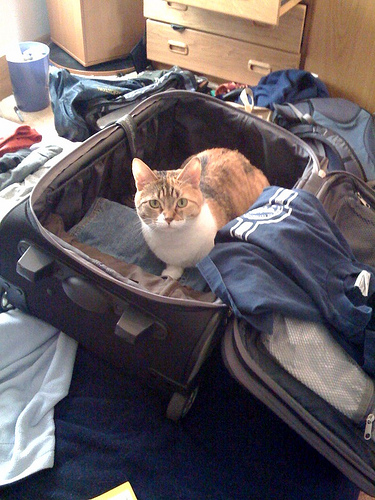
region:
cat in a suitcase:
[27, 92, 318, 351]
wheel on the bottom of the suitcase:
[155, 383, 211, 430]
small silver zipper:
[363, 416, 372, 441]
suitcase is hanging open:
[16, 67, 373, 495]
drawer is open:
[166, 0, 323, 24]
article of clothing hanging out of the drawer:
[171, 24, 190, 30]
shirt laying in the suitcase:
[196, 178, 373, 332]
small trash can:
[6, 40, 55, 113]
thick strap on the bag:
[285, 118, 367, 180]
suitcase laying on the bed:
[0, 88, 372, 495]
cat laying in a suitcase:
[0, 90, 374, 484]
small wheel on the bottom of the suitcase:
[158, 384, 206, 426]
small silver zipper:
[361, 412, 373, 442]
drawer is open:
[179, 0, 313, 28]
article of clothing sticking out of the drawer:
[168, 21, 184, 33]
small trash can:
[5, 33, 56, 115]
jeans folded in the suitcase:
[66, 191, 223, 296]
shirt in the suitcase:
[195, 184, 373, 342]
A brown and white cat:
[129, 148, 271, 279]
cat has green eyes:
[145, 197, 187, 208]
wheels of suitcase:
[0, 283, 197, 422]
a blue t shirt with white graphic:
[196, 182, 372, 314]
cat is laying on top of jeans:
[61, 148, 267, 298]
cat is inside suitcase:
[11, 79, 333, 351]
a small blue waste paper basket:
[4, 37, 54, 112]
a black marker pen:
[10, 106, 24, 121]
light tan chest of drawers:
[141, 5, 307, 91]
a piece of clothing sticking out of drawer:
[167, 19, 188, 32]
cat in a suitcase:
[129, 132, 274, 288]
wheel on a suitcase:
[157, 368, 210, 444]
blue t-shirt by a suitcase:
[218, 170, 369, 374]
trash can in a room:
[2, 34, 58, 110]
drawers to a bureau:
[131, 1, 299, 100]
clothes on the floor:
[46, 57, 176, 132]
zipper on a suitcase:
[352, 409, 373, 439]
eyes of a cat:
[144, 193, 193, 213]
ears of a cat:
[124, 150, 213, 188]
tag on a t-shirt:
[353, 261, 372, 306]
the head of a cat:
[129, 148, 232, 250]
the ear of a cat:
[131, 156, 210, 198]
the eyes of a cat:
[126, 182, 208, 229]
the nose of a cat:
[150, 205, 184, 238]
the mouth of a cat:
[145, 208, 212, 241]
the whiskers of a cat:
[131, 199, 207, 236]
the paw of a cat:
[155, 246, 200, 293]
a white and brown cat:
[116, 132, 279, 257]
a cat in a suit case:
[120, 112, 285, 273]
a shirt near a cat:
[92, 153, 302, 327]